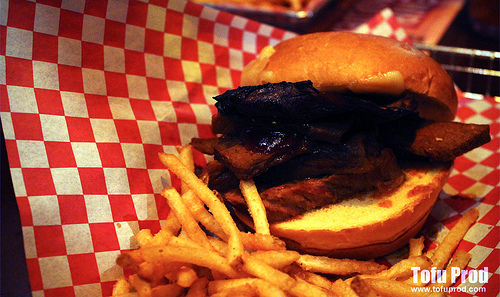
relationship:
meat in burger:
[219, 90, 497, 187] [221, 76, 483, 241]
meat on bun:
[219, 90, 497, 187] [232, 31, 463, 116]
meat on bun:
[219, 90, 497, 187] [268, 161, 449, 246]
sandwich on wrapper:
[200, 31, 462, 255] [6, 19, 498, 295]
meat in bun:
[219, 90, 497, 187] [211, 30, 451, 252]